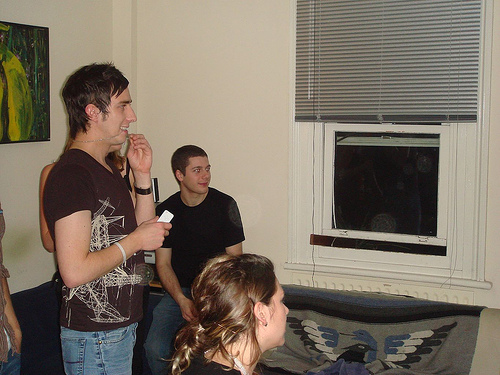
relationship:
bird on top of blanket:
[287, 315, 460, 374] [290, 284, 488, 374]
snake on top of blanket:
[334, 328, 382, 343] [290, 284, 488, 374]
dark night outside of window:
[342, 151, 426, 222] [326, 123, 451, 246]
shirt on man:
[156, 188, 247, 287] [142, 144, 247, 372]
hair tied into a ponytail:
[162, 253, 275, 375] [157, 309, 209, 373]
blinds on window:
[293, 1, 481, 123] [326, 123, 451, 246]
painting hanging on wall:
[0, 20, 51, 143] [1, 1, 58, 159]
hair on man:
[171, 144, 209, 184] [142, 144, 247, 372]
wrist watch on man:
[132, 184, 154, 197] [40, 60, 174, 374]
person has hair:
[40, 60, 174, 374] [60, 61, 131, 141]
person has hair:
[142, 144, 247, 372] [171, 144, 209, 184]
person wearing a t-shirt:
[40, 60, 174, 374] [43, 149, 148, 333]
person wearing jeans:
[40, 60, 174, 374] [58, 322, 139, 372]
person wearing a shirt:
[142, 144, 247, 372] [156, 188, 247, 287]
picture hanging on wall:
[0, 20, 51, 143] [1, 1, 58, 159]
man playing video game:
[40, 60, 174, 374] [157, 210, 174, 223]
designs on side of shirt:
[59, 200, 143, 329] [43, 149, 148, 333]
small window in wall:
[326, 123, 451, 246] [247, 0, 500, 253]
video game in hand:
[157, 210, 174, 223] [135, 215, 173, 252]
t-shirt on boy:
[156, 188, 247, 287] [142, 144, 247, 372]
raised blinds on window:
[293, 1, 481, 123] [326, 123, 451, 246]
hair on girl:
[162, 253, 275, 375] [157, 252, 279, 374]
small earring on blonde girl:
[262, 320, 271, 328] [157, 252, 279, 374]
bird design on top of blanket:
[287, 315, 460, 374] [290, 284, 488, 374]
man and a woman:
[142, 144, 247, 372] [157, 252, 279, 374]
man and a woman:
[40, 60, 174, 374] [157, 252, 279, 374]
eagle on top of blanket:
[287, 315, 460, 374] [290, 284, 488, 374]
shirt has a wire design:
[43, 149, 148, 333] [59, 200, 143, 329]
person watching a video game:
[157, 252, 279, 374] [157, 208, 175, 221]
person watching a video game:
[142, 144, 247, 372] [157, 208, 175, 221]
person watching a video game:
[0, 207, 23, 374] [157, 208, 175, 221]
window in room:
[326, 123, 451, 246] [1, 1, 500, 374]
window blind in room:
[293, 1, 481, 123] [1, 1, 500, 374]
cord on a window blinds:
[309, 1, 317, 286] [293, 1, 481, 123]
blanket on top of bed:
[290, 284, 488, 374] [288, 284, 499, 374]